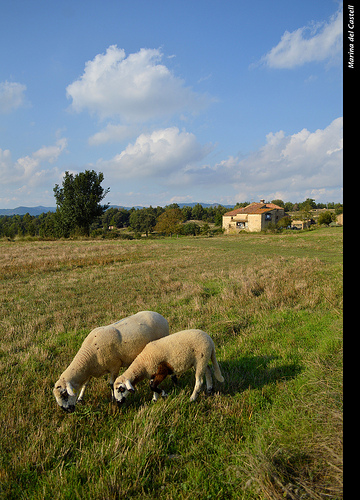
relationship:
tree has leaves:
[53, 169, 111, 241] [62, 179, 100, 223]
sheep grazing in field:
[111, 328, 226, 406] [2, 242, 342, 500]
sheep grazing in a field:
[53, 314, 108, 414] [2, 242, 342, 500]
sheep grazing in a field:
[111, 328, 226, 406] [2, 242, 342, 500]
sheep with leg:
[111, 328, 226, 406] [150, 362, 174, 398]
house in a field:
[221, 201, 287, 235] [0, 199, 342, 498]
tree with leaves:
[53, 169, 111, 241] [62, 179, 100, 223]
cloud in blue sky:
[66, 44, 217, 128] [3, 1, 252, 124]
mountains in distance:
[1, 201, 219, 215] [0, 201, 223, 219]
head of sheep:
[51, 377, 87, 413] [53, 314, 108, 414]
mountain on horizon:
[1, 201, 219, 215] [0, 188, 223, 217]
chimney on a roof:
[257, 197, 268, 206] [223, 203, 283, 214]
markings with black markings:
[117, 386, 128, 395] [117, 385, 126, 394]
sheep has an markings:
[111, 328, 226, 406] [117, 386, 128, 395]